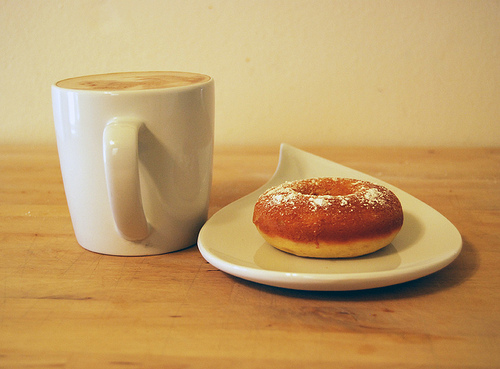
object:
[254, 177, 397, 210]
sugar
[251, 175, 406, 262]
doughnut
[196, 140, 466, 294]
plate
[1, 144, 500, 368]
table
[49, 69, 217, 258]
mug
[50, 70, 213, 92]
liquid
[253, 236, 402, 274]
shadow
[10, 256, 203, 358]
scratches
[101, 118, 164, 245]
handle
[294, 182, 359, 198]
hole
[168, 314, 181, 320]
spots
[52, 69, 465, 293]
cup and plate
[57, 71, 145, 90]
cream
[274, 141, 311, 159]
point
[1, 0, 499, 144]
wall